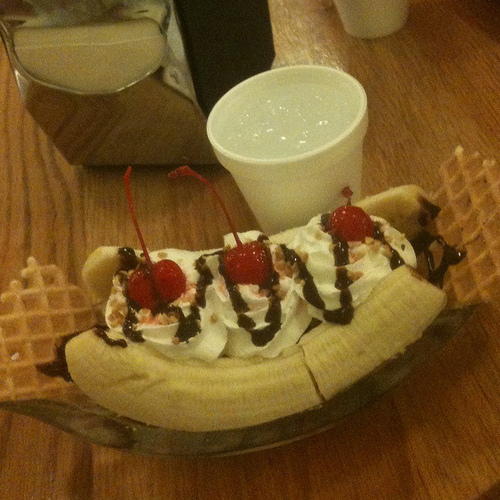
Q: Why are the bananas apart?
A: A banana split.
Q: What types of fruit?
A: Bananas and cherries.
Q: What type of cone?
A: A waffle cone.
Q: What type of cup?
A: A styrofoam cup.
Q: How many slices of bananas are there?
A: There are two.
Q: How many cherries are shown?
A: There are three shown.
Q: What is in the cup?
A: Ice with water.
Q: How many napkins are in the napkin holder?
A: There is a lot.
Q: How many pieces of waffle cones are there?
A: There are two.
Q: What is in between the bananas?
A: Whip cream.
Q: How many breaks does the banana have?
A: It has one.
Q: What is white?
A: Whipped cream.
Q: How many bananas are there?
A: Two.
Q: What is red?
A: Cherries.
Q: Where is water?
A: In a cup.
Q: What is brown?
A: Chocolate syrup.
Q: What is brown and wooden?
A: Table.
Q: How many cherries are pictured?
A: Three.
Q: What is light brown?
A: Waffles.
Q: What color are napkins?
A: White.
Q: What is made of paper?
A: The cup.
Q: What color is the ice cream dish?
A: Clear.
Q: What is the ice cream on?
A: A banana split.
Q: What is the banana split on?
A: A waffle cone.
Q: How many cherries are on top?
A: Three.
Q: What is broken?
A: Half a banana.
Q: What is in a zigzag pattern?
A: Chocolate syrup.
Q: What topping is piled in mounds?
A: Whipped cream.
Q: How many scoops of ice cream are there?
A: Three.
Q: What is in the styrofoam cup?
A: A drink.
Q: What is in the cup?
A: Water with ice.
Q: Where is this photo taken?
A: At a table.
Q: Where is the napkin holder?
A: Behind the cup.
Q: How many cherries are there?
A: Three.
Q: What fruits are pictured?
A: Cherries and bananas.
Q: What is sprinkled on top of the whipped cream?
A: Nuts.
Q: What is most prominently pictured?
A: A banana split.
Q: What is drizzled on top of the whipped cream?
A: Chocolate sauce.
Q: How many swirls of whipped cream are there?
A: Three.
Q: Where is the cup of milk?
A: Behind the banana split.